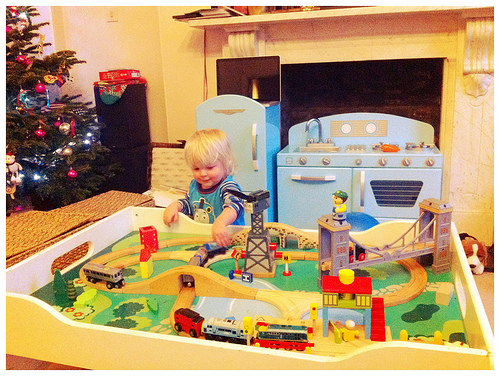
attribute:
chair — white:
[192, 93, 281, 222]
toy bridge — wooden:
[315, 188, 453, 284]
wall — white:
[79, 30, 145, 64]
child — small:
[163, 122, 254, 257]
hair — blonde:
[182, 124, 235, 177]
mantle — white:
[186, 4, 492, 27]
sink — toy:
[279, 110, 443, 230]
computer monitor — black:
[215, 57, 282, 102]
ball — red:
[61, 158, 93, 188]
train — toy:
[172, 307, 314, 352]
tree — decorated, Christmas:
[9, 29, 109, 216]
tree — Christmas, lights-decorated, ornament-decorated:
[6, 7, 125, 219]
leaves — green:
[76, 136, 126, 179]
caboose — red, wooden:
[169, 301, 206, 343]